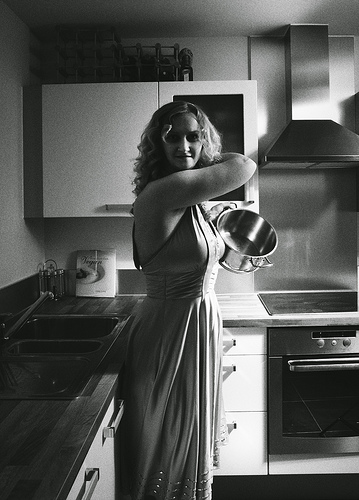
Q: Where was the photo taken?
A: The kitchen.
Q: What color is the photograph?
A: Black and white.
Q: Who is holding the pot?
A: The woman.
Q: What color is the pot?
A: Silver.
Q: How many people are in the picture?
A: One.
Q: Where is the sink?
A: To the left of the woman.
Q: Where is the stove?
A: Behind the woman.